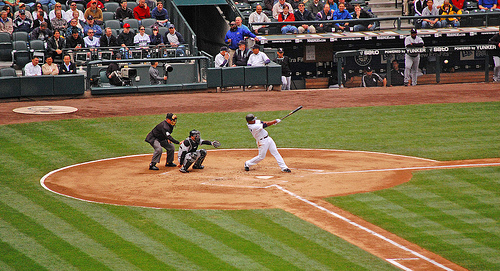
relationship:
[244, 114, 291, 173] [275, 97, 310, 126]
batter swinging bat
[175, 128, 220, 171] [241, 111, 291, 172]
catcher behind batter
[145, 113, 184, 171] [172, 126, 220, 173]
umpire behind catcher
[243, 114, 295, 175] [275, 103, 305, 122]
batter swinging bat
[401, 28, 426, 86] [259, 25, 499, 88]
person in dugout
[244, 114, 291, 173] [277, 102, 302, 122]
batter swinging bat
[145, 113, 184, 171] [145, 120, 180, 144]
umpire wearing black shirt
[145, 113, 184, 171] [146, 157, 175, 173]
umpire wearing shoes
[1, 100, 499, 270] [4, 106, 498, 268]
grass has stripes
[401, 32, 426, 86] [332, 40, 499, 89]
person by fence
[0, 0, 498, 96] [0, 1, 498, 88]
people in stands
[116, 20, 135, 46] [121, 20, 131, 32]
man wearing hat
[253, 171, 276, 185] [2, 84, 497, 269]
homeplate on ground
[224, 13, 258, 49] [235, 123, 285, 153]
people are wearing shirts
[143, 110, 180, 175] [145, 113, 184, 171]
umpire behind umpire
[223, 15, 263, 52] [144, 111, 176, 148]
men wearing jackets